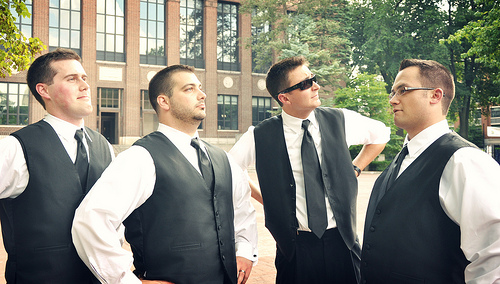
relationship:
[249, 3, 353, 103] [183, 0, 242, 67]
tree on window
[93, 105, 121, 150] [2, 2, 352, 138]
door on building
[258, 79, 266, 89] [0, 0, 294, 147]
white circle on building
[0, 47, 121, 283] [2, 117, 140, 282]
guy on vest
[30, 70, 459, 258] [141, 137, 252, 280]
four men on black vest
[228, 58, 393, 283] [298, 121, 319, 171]
guy on tie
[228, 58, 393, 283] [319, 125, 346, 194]
guy on vest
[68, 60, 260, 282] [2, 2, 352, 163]
guy on building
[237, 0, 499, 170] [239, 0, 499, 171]
leaves on trees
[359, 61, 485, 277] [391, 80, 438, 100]
man wearing spectacles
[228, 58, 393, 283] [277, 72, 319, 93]
guy wearing spectacles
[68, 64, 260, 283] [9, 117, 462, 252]
guy wearing vests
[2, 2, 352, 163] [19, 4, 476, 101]
building in background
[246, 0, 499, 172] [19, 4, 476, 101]
tree are in background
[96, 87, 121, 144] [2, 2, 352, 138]
door of building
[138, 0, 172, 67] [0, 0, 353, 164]
window of building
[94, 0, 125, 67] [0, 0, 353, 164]
window of building